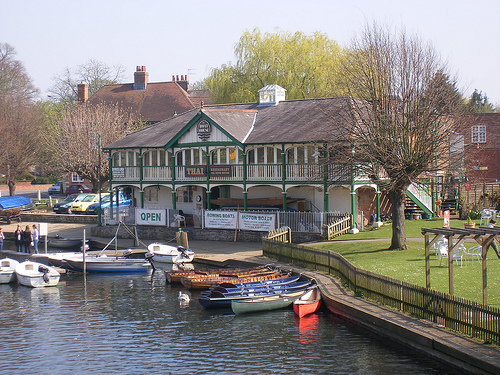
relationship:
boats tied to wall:
[165, 264, 323, 321] [2, 230, 499, 375]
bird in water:
[178, 292, 190, 308] [1, 256, 499, 374]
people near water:
[1, 225, 40, 254] [1, 256, 499, 374]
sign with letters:
[133, 208, 168, 227] [140, 212, 162, 221]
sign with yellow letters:
[184, 165, 232, 179] [187, 168, 232, 174]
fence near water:
[261, 224, 500, 348] [1, 256, 499, 374]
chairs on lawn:
[430, 236, 485, 269] [298, 219, 500, 346]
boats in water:
[165, 264, 323, 321] [1, 256, 499, 374]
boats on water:
[165, 264, 323, 321] [1, 256, 499, 374]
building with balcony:
[102, 86, 434, 232] [111, 163, 388, 182]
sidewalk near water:
[2, 220, 499, 374] [1, 256, 499, 374]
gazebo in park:
[424, 224, 500, 325] [298, 219, 500, 346]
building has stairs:
[102, 86, 434, 232] [397, 181, 436, 221]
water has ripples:
[1, 256, 499, 374] [2, 305, 444, 374]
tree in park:
[300, 15, 487, 252] [298, 219, 500, 346]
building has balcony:
[102, 86, 434, 232] [111, 163, 388, 182]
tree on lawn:
[300, 15, 487, 252] [298, 219, 500, 346]